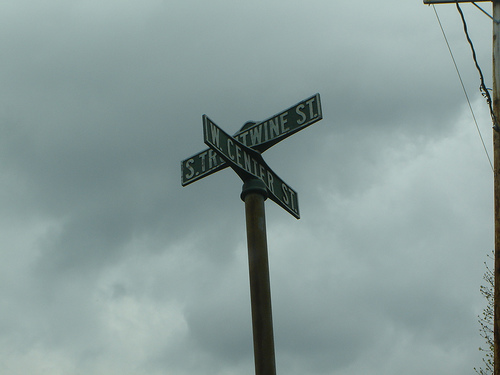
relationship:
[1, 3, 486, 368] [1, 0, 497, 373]
clouds in sky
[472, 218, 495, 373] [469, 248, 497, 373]
branches in corner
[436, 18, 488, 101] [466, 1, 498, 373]
wires on pole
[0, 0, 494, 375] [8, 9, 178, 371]
clouds in sky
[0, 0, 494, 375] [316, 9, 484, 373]
clouds in sky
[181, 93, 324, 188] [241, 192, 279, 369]
sign on pole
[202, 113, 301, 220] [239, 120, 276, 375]
sign on metal pole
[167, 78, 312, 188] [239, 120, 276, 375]
sign on metal pole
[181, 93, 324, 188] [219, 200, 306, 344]
sign on pole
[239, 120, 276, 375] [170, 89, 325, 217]
metal pole with signs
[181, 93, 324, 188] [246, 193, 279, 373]
sign with pole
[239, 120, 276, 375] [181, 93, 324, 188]
metal pole with sign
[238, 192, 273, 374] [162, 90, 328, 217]
metal pole beneath sign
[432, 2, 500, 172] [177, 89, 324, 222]
wires behind sign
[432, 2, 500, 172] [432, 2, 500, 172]
wires behind wires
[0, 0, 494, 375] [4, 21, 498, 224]
clouds in sky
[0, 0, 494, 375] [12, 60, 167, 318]
clouds in sky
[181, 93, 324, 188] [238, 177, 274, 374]
sign on pole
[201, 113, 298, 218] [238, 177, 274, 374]
sign on pole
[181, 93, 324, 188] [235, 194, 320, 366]
sign on pole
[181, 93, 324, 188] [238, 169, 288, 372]
sign on pole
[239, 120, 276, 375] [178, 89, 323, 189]
metal pole with street sign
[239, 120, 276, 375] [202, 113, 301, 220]
metal pole with sign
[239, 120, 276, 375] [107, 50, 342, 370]
metal pole with signs